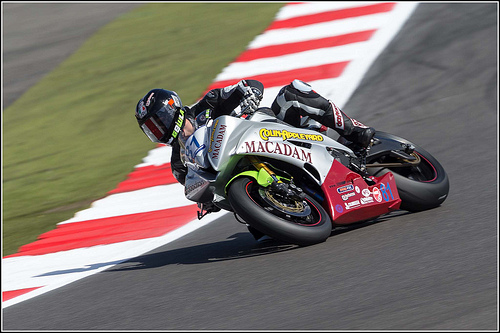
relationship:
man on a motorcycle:
[136, 81, 375, 213] [196, 107, 450, 247]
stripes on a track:
[1, 1, 419, 328] [1, 1, 500, 330]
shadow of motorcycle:
[34, 233, 296, 272] [196, 107, 450, 247]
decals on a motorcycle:
[329, 173, 395, 215] [196, 107, 450, 247]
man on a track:
[136, 81, 375, 213] [1, 1, 500, 330]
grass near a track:
[2, 2, 285, 258] [1, 1, 500, 330]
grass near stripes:
[2, 2, 285, 258] [1, 1, 419, 328]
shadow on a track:
[34, 233, 296, 272] [1, 1, 500, 330]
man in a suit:
[136, 81, 375, 213] [169, 79, 366, 208]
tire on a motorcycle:
[228, 177, 333, 245] [196, 107, 450, 247]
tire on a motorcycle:
[338, 128, 450, 213] [196, 107, 450, 247]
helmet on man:
[136, 88, 186, 145] [136, 81, 375, 213]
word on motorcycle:
[260, 128, 324, 144] [196, 107, 450, 247]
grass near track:
[2, 2, 285, 258] [1, 1, 500, 330]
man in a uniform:
[136, 81, 375, 213] [169, 79, 366, 208]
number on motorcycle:
[182, 136, 202, 163] [196, 107, 450, 247]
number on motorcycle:
[381, 183, 397, 204] [196, 107, 450, 247]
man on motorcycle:
[136, 81, 375, 213] [196, 107, 450, 247]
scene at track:
[0, 0, 500, 333] [1, 1, 500, 330]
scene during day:
[14, 5, 484, 293] [20, 13, 465, 295]